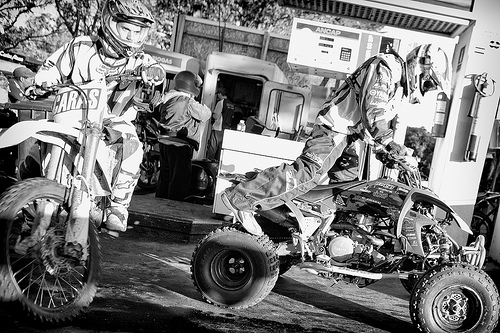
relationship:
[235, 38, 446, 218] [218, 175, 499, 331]
rider on motorcycle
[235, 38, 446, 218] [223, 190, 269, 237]
rider has foot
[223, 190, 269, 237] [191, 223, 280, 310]
foot on tire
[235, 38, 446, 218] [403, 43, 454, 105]
rider wearing helmet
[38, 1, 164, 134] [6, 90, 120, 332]
man riding dirtbike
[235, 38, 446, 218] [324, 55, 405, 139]
rider wearing jersey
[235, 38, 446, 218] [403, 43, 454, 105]
man wearing helmet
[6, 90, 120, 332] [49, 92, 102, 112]
dirtbike has sticker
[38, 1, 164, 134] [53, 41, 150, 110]
man wearing jacket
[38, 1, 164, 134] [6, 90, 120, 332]
man on dirtbike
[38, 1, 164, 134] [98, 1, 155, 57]
man wearing helmet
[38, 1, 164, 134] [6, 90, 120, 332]
man sitting on top of dirtbike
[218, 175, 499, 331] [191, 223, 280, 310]
motorcycle has wheel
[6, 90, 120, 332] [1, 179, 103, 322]
bike has wheel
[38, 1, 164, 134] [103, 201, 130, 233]
man wearing shoes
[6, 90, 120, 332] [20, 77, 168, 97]
bike has handle bars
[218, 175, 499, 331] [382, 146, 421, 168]
4 wheeler has handle bars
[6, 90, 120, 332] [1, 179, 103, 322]
bike has tire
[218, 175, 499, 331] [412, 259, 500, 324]
4 wheeler has tire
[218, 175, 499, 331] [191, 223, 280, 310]
4 wheeler has tire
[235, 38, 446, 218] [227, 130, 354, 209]
rider wearing pants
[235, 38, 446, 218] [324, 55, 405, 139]
rider wearing jacket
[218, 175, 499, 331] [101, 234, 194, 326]
atv on top of road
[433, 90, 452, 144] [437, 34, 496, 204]
fire extinguisher hanging on wall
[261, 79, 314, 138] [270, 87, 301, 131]
door has window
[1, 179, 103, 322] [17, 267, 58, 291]
tire has spokes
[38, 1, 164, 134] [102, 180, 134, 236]
man wearing boots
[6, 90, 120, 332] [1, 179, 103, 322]
dirtbike has tire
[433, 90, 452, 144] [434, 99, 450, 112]
fire extinguisher has label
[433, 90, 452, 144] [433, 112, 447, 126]
fire extinguisher has label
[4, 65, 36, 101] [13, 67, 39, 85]
man wearing hat